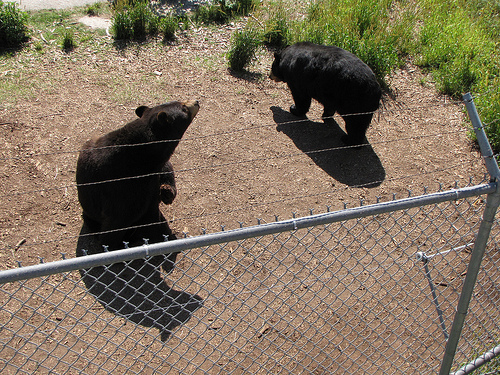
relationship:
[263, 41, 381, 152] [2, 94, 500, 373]
bear beside fencing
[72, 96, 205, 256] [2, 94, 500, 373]
bear beside fencing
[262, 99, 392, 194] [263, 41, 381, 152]
shadow of bear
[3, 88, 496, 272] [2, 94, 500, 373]
wire on top of fencing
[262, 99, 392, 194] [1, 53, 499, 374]
shadow on soil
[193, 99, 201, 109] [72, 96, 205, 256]
snout of bear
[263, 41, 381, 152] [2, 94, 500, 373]
bear behind fencing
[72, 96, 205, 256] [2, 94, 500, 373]
bear behind fencing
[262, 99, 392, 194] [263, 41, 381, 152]
shadow by bear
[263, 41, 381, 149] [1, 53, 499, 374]
bear looking at soil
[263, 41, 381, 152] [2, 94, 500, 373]
bear in fencing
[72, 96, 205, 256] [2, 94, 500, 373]
bear in fencing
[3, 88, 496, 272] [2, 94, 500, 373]
wire top of fencing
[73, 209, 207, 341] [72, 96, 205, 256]
shadow of bear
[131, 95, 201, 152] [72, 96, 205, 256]
head of bear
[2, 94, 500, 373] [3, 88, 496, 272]
fencing with wire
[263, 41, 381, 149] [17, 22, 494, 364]
bear in forest